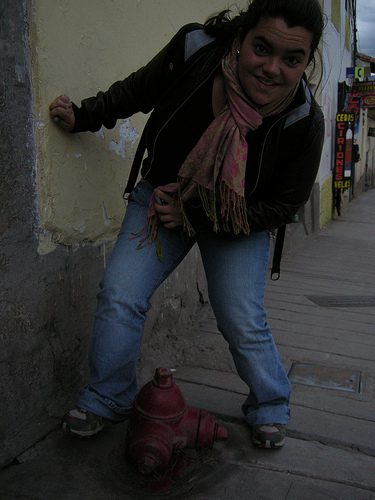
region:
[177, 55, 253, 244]
pink scarve around woman's neck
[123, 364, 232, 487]
red fire hydrant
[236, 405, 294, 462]
gray and black shoe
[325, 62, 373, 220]
colorful signs on the side of the building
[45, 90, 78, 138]
woman's left hand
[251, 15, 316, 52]
woman's wrinkled forehead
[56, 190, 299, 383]
blue jeans on the woman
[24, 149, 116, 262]
yellow cement wall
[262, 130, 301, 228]
part of woman's black jacket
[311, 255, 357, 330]
gray wooden sidewalk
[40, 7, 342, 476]
lady wearing a scarf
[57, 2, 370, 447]
lady wearing a black shirt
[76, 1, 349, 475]
lady wearing a black jacket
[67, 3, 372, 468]
lady wearing light blue denim jeans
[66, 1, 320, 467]
lady wearing tennis shoes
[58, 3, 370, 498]
lady near a red fire hydrant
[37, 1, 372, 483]
lady leaning to the side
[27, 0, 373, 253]
lady hand on the wall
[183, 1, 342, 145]
lady smiling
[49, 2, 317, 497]
lady almost falling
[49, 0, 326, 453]
woman standing over fire hydrant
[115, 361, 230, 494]
red fire hydrant on ground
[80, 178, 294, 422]
blue jeans on woman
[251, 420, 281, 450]
gray tennis shoe on left foot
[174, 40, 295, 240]
pink and green scarf around woman's neck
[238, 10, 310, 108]
face of woman is smiling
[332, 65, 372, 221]
signs in the background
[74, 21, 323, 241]
black jacket on woman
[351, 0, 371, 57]
gray cloudy sky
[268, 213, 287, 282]
strap of woman's backpack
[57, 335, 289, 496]
a firy hydrant in the ground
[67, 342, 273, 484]
a hydrant in the ground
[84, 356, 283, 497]
a fire hydrant on the sidewalk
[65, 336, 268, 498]
a hydrant on their sidewalk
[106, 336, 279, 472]
a red fire hydrant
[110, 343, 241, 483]
a red fire hydrant in the ground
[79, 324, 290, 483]
a red hydrant in the ground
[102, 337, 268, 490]
a red fire hydrant on the sidewalk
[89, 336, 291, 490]
a red hydrant on a sidewalk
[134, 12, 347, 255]
a woman wearing a scarf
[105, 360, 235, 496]
A red fire hydrant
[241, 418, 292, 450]
Grey tennis shoe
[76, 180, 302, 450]
Blue jeans on a person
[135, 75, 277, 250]
Scarf on a persons neck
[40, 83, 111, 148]
Hand against the wall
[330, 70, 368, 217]
Signs on a sidewalk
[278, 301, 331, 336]
Surface of the sidewalk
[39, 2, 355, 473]
A woman standing over a fire hydrant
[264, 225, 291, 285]
Buckle hanging off of a jacket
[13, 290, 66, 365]
Cement wall of a building